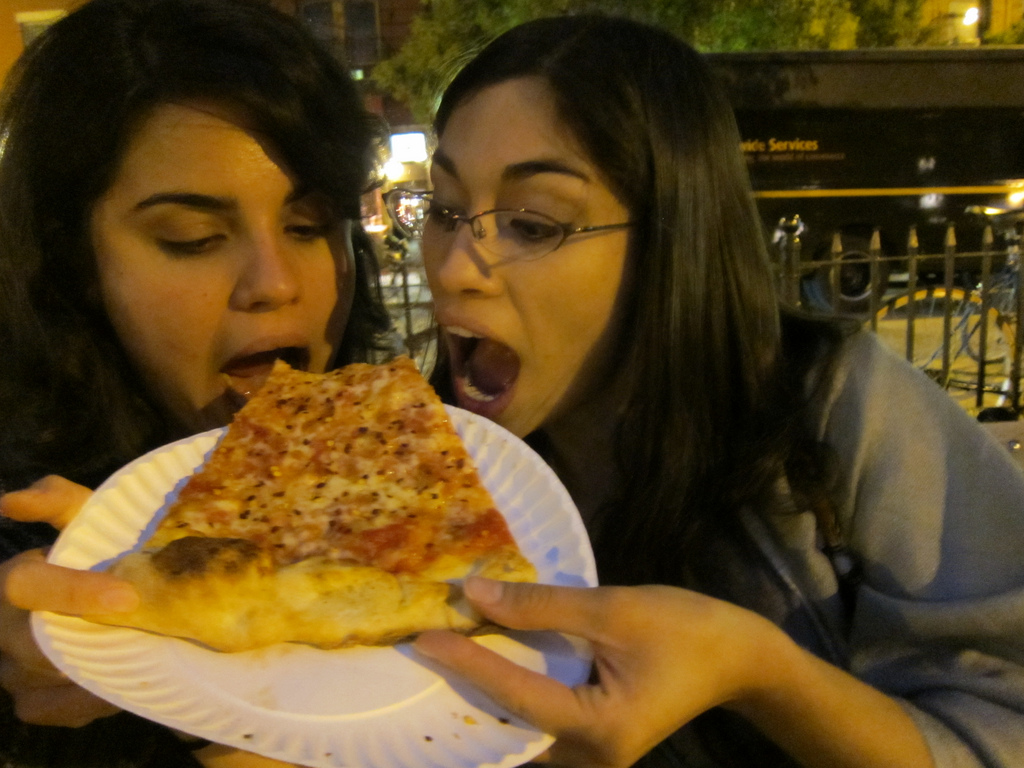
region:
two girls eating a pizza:
[33, 41, 1011, 766]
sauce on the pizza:
[373, 527, 415, 565]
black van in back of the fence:
[735, 35, 1021, 194]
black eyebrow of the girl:
[119, 183, 249, 215]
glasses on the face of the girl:
[406, 184, 612, 255]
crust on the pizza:
[182, 582, 332, 643]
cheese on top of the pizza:
[311, 436, 387, 532]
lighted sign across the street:
[386, 124, 435, 169]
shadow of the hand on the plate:
[539, 632, 596, 686]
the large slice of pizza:
[101, 358, 544, 654]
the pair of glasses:
[392, 181, 655, 262]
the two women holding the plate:
[2, 6, 1018, 766]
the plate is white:
[32, 417, 598, 766]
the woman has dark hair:
[385, 15, 1022, 766]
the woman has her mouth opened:
[411, 2, 1019, 764]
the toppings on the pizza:
[103, 350, 550, 652]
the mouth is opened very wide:
[436, 313, 526, 421]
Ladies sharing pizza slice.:
[5, 8, 982, 752]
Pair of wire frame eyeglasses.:
[379, 174, 636, 250]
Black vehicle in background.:
[719, 48, 1023, 309]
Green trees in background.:
[375, 0, 1023, 112]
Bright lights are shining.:
[372, 89, 449, 279]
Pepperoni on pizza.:
[353, 494, 515, 568]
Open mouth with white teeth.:
[435, 311, 530, 423]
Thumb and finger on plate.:
[406, 545, 762, 749]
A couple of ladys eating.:
[18, 69, 812, 759]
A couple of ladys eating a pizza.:
[24, 1, 758, 758]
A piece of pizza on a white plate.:
[34, 353, 620, 761]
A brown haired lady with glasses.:
[397, 15, 765, 453]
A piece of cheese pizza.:
[65, 357, 537, 639]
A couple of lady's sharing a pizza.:
[15, 6, 788, 752]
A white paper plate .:
[27, 404, 600, 759]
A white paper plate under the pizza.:
[25, 353, 605, 761]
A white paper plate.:
[27, 402, 598, 763]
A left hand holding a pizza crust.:
[409, 574, 763, 764]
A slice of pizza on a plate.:
[90, 353, 534, 652]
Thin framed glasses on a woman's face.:
[387, 184, 644, 261]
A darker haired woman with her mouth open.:
[0, 1, 397, 766]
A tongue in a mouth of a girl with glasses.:
[469, 336, 521, 395]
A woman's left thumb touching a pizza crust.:
[459, 576, 605, 634]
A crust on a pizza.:
[102, 555, 537, 651]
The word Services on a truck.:
[766, 134, 818, 151]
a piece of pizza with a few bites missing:
[106, 350, 543, 646]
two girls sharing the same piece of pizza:
[2, 1, 1021, 766]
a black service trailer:
[701, 47, 1021, 311]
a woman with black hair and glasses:
[419, 14, 1021, 767]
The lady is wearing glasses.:
[407, 167, 651, 256]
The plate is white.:
[47, 592, 626, 766]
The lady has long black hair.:
[597, 94, 788, 453]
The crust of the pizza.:
[54, 575, 530, 656]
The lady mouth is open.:
[420, 312, 538, 411]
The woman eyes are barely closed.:
[136, 196, 380, 279]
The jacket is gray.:
[780, 367, 989, 618]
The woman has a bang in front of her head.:
[174, 80, 386, 191]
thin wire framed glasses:
[381, 175, 635, 270]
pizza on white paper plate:
[27, 400, 607, 765]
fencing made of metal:
[775, 200, 1023, 417]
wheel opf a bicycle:
[959, 255, 1023, 380]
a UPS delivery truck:
[690, 43, 1022, 313]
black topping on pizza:
[452, 487, 472, 511]